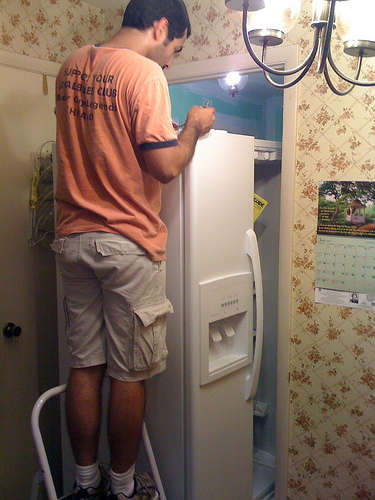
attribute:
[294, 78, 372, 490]
wallpaper — floral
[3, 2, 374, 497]
wallpaper — beige, floral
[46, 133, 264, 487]
refrigerator — white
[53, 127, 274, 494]
refrigerator — missing a door, white, stuck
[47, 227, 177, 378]
cargo shorts — tan, khaki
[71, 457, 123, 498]
socks — cotton, white, tube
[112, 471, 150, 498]
sneaker — grey, blue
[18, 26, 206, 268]
shirt — orange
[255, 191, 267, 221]
paper — yellow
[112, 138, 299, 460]
freezer — white , metal 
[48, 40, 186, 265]
tee shirt — orange, cotton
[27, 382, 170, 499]
step stool — white, metal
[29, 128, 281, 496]
refrigerator — white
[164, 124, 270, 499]
door — for water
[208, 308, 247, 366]
dispenser — for ice